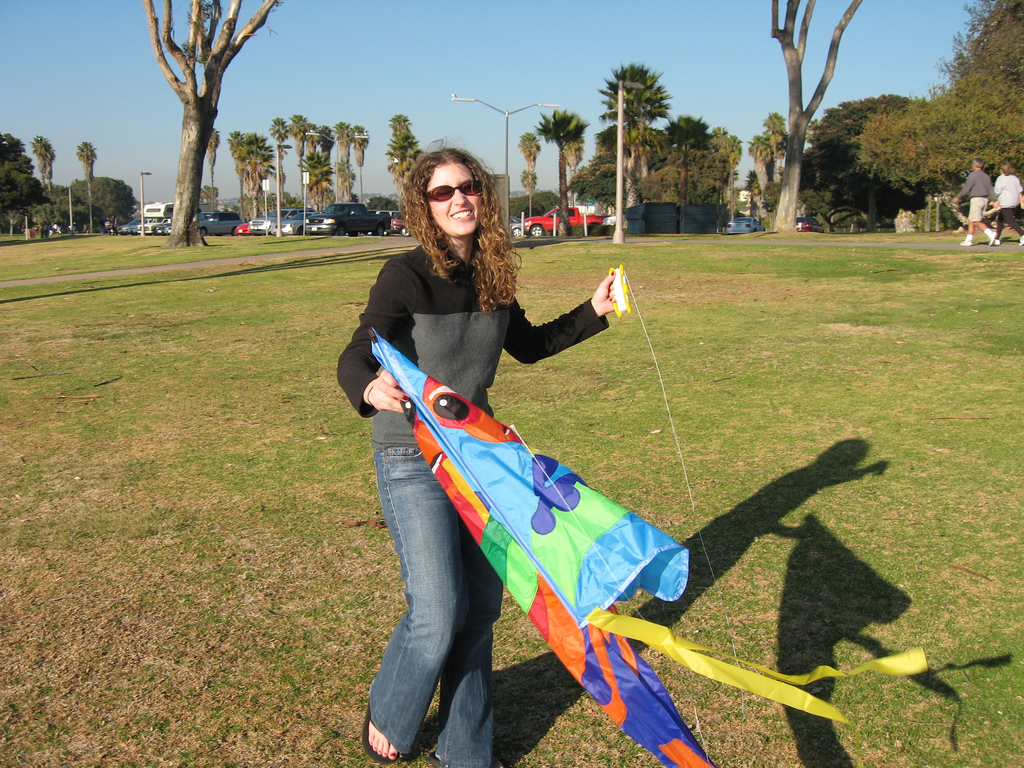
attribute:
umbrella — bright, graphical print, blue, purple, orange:
[363, 317, 929, 766]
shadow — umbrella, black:
[777, 510, 1012, 766]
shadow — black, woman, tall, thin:
[481, 409, 892, 765]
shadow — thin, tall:
[438, 440, 890, 766]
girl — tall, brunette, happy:
[334, 142, 638, 766]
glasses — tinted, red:
[424, 178, 481, 202]